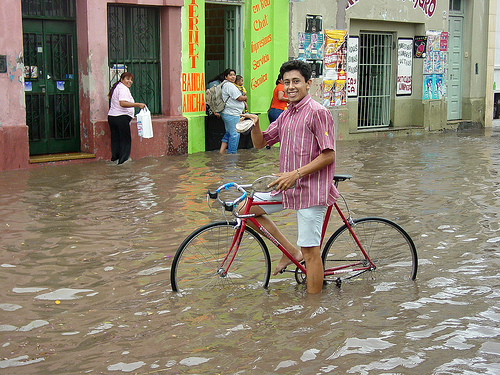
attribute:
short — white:
[233, 179, 345, 259]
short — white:
[263, 173, 343, 254]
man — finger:
[228, 51, 334, 305]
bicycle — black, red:
[171, 168, 430, 301]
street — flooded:
[23, 230, 132, 343]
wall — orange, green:
[190, 10, 270, 134]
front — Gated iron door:
[359, 40, 398, 122]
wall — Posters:
[349, 27, 414, 107]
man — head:
[265, 60, 324, 104]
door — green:
[13, 0, 105, 158]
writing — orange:
[179, 0, 216, 98]